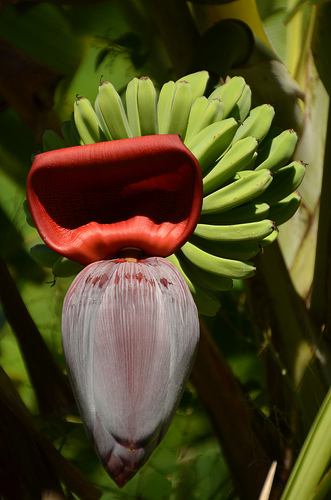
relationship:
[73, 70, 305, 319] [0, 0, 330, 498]
banana growing on tree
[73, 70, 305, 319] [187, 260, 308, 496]
banana growing on tree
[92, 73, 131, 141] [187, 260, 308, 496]
banana growing on tree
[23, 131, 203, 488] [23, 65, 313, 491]
red color in fruit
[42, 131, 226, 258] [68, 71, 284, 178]
top part of banana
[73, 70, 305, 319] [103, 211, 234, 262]
banana about to come out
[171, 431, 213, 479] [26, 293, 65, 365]
leaves in back